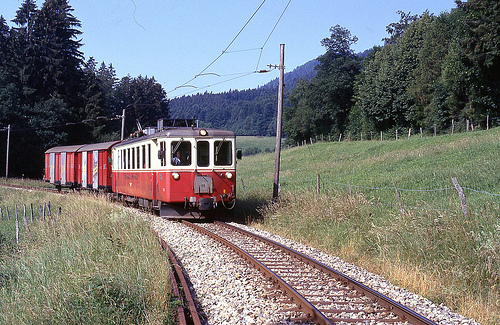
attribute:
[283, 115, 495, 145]
fence — metal, large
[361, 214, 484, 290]
grass — brown, dead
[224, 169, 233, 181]
light — front light, small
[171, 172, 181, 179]
light — small, front light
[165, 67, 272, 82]
wires — electrical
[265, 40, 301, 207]
pole — electrical, grey, wood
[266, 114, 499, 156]
fencing — steel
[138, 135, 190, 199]
door — red, white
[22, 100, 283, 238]
train — white, red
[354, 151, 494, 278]
grass — green, tall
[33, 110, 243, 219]
train — white, red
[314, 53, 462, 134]
trees — tall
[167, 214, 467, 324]
path — stone path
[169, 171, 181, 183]
headlight — round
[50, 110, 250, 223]
train — short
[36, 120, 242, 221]
train — red, white, old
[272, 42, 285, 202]
pole — electrical pole